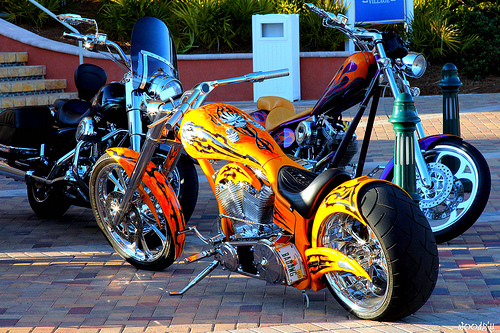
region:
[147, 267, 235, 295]
kick stand on motorcyce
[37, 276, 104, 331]
part of brick pavement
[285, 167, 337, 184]
seat on the motorcycle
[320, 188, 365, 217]
yellow fender on motorcycle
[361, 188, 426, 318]
tire on the motorcycle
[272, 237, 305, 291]
license plate on motorcycle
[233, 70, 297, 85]
handlebar on the motorcycle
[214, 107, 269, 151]
design on the motorcycle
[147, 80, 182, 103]
light on the motorcycle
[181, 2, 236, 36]
trees behind the motorcycles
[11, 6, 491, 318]
Three parked motorcycles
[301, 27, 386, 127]
Flames painted on motorcycle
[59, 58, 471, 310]
Orange painted motorcycle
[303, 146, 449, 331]
Large back tire on motorcycle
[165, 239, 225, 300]
Kick stand on motorcycle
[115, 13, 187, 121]
Windshield on motorcycle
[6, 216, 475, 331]
Brick pavers on the ground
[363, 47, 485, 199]
Two green poles near the motorcycles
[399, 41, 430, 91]
Headlight on motorcycle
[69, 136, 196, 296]
Front tire of motorcycle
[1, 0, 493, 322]
three motorcycles parked outside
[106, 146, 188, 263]
yellow and black front tire cover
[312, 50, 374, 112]
purple and orange design on bike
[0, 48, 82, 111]
tan stone steps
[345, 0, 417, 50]
a blue and white sign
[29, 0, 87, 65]
a thin white railing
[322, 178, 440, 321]
extra thick back tire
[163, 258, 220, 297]
silver kick stand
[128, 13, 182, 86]
window on front of bike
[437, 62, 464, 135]
a dark green short post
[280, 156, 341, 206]
black motorcycle seat cover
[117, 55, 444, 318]
Motorcycle is large and orange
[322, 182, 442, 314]
Black tire is big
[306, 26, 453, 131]
Other motorcycle in background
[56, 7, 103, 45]
Right brake handle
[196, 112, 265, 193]
Orange flame design on body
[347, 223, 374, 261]
Spokes of back wheel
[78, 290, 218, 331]
Bricks on pavement below bike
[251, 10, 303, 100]
White post box in background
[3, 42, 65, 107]
Stairs behind bikes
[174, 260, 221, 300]
Bike has kickstand